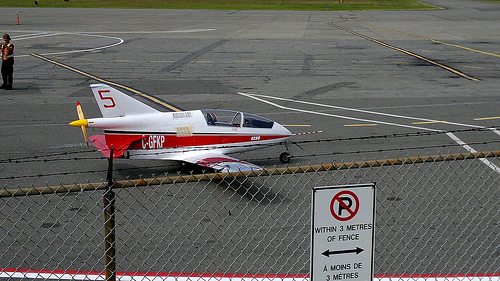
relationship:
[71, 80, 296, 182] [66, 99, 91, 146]
plane has propeller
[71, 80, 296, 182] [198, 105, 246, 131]
plane has cockpit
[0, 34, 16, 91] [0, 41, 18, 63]
man wearing vest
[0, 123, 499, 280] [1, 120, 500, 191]
fence has wire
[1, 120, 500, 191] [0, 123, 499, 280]
wire on top of fence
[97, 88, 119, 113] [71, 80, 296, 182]
number on plane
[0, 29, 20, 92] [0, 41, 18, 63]
man in vest